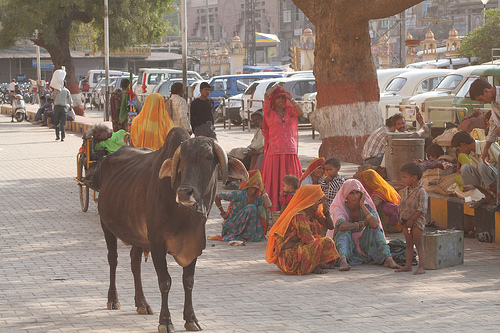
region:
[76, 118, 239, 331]
cow standing on brick sidewalk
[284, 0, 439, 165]
large tree trunk painted orange and white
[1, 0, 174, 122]
large tree with orange and white painted trunk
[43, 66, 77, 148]
man carrying package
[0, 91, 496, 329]
long red brick sidewalk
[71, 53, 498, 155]
row of parked cars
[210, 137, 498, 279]
women and children sitting on brick sidewalk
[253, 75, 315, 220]
woman in red outfit standing on sidewalk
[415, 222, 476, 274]
small suitcase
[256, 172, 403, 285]
woman in orange outfit and veil sitting next to woman in blue outfit and pink veil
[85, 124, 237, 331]
cattle with downward facing horns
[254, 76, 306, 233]
women wearing pink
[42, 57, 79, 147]
man carrying a large bag on his shoulder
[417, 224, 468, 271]
gray metal box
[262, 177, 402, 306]
people sitting on the ground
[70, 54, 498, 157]
long row of cars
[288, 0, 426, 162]
large tree trunk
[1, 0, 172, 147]
large tree in the city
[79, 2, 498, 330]
people gathered together in a city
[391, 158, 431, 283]
barefoot little boy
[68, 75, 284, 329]
a cow at the sidewalk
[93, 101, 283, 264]
the cow is brown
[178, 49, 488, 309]
people are sitting at the sidewalk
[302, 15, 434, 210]
the tree is painted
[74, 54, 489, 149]
the cars are parked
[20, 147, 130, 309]
shadow on the street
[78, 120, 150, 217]
the man is sleeping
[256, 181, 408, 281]
women are wearing saris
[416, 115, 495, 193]
the men are sitting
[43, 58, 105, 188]
a man carrying white bag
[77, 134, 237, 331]
The animal is standing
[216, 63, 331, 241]
The woman has a red outfit on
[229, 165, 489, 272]
The people are sitting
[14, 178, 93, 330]
The ground is made of stone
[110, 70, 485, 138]
The cars are parked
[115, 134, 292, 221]
The animal has horns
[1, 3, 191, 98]
The tree is green and tall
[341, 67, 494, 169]
The men are looking down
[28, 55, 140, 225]
The man is carrying a large bag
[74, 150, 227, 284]
The animal is brown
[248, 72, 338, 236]
woman wearing all red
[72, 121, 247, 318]
brown animal in street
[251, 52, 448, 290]
many people gathered under tree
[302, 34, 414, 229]
brown tree with red and white stripes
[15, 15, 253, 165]
three lamp poles on street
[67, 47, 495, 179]
many cars parked on street side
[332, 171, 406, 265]
woman with pink shawl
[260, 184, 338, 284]
woman in orange shawl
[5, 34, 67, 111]
building in background of photo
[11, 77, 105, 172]
people walking in photograph